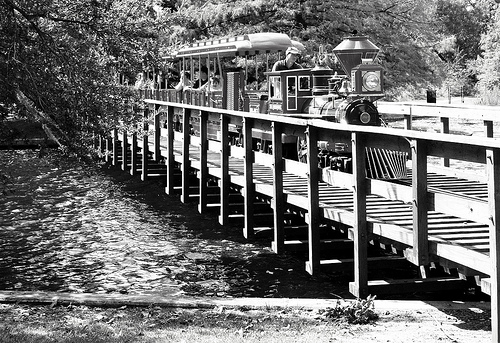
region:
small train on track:
[199, 19, 422, 177]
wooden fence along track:
[131, 65, 495, 274]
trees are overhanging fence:
[15, 3, 177, 144]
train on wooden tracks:
[311, 165, 497, 245]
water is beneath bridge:
[1, 139, 348, 266]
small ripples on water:
[5, 158, 126, 279]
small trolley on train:
[140, 42, 255, 132]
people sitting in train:
[143, 64, 232, 103]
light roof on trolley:
[160, 28, 285, 60]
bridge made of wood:
[87, 91, 496, 341]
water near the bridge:
[0, 150, 345, 295]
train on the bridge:
[165, 34, 412, 180]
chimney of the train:
[335, 33, 379, 75]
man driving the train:
[272, 45, 302, 72]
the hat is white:
[287, 46, 301, 53]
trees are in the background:
[1, 1, 496, 112]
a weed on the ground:
[332, 293, 377, 319]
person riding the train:
[175, 70, 190, 90]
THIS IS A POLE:
[412, 138, 427, 247]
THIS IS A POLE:
[303, 133, 318, 273]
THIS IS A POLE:
[272, 121, 280, 259]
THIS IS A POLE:
[241, 113, 250, 255]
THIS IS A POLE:
[217, 108, 228, 224]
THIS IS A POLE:
[164, 102, 175, 194]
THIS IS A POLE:
[136, 107, 150, 176]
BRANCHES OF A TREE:
[37, 5, 74, 87]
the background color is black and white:
[121, 80, 315, 262]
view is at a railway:
[220, 36, 494, 244]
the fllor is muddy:
[56, 182, 215, 297]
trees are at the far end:
[391, 23, 496, 82]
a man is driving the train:
[272, 28, 307, 109]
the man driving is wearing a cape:
[270, 33, 333, 93]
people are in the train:
[175, 51, 259, 119]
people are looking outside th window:
[159, 52, 236, 112]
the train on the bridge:
[107, 29, 407, 179]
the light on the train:
[365, 74, 379, 88]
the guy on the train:
[270, 45, 302, 70]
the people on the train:
[147, 68, 219, 88]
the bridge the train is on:
[75, 98, 499, 341]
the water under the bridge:
[0, 147, 499, 300]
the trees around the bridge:
[0, 0, 498, 179]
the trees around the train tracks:
[0, 0, 499, 177]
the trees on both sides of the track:
[0, 0, 499, 170]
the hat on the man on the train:
[285, 45, 300, 55]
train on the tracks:
[123, 19, 429, 188]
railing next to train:
[77, 57, 499, 276]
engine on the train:
[313, 91, 396, 147]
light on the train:
[355, 64, 385, 95]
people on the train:
[127, 68, 207, 92]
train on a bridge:
[68, 5, 493, 293]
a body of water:
[12, 132, 229, 312]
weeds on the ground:
[320, 290, 386, 325]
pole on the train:
[193, 55, 203, 92]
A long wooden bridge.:
[76, 88, 498, 305]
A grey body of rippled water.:
[1, 144, 491, 296]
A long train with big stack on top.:
[144, 33, 413, 182]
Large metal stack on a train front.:
[333, 34, 380, 82]